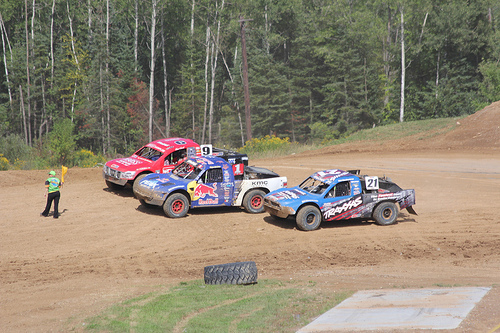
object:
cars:
[132, 155, 288, 219]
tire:
[200, 261, 258, 286]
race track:
[0, 142, 499, 329]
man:
[41, 170, 63, 218]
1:
[231, 163, 243, 176]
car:
[101, 137, 233, 194]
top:
[182, 155, 231, 171]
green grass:
[82, 277, 351, 331]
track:
[3, 233, 498, 286]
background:
[0, 0, 499, 324]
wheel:
[242, 190, 268, 214]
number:
[363, 175, 379, 190]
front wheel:
[295, 204, 321, 231]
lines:
[56, 246, 162, 279]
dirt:
[1, 93, 483, 329]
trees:
[4, 0, 500, 167]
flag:
[61, 165, 68, 185]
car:
[261, 168, 418, 231]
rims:
[163, 193, 190, 217]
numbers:
[201, 144, 214, 156]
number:
[233, 163, 241, 175]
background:
[230, 160, 240, 171]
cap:
[49, 169, 58, 177]